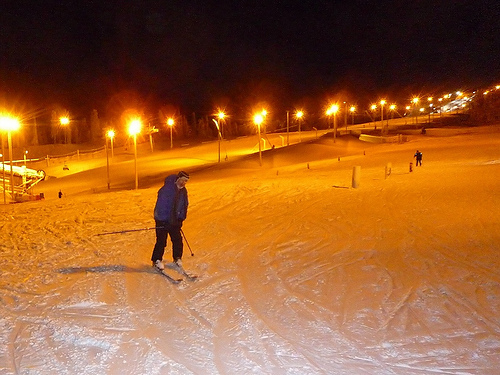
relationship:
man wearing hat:
[149, 169, 190, 272] [173, 170, 188, 182]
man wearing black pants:
[149, 169, 190, 272] [150, 225, 182, 263]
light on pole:
[126, 119, 141, 133] [129, 135, 143, 182]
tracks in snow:
[237, 263, 294, 344] [0, 109, 497, 373]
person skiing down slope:
[393, 110, 447, 204] [6, 124, 498, 373]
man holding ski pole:
[149, 169, 190, 272] [88, 224, 169, 239]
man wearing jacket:
[153, 167, 192, 275] [149, 172, 189, 227]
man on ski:
[149, 169, 190, 272] [157, 269, 182, 284]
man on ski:
[149, 169, 190, 272] [175, 261, 196, 280]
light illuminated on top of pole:
[125, 119, 141, 135] [124, 135, 143, 190]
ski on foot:
[153, 268, 186, 284] [153, 256, 165, 267]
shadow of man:
[55, 265, 157, 277] [151, 169, 192, 270]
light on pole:
[125, 119, 141, 135] [132, 138, 139, 190]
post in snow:
[352, 165, 361, 189] [0, 109, 497, 373]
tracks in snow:
[125, 257, 207, 373] [0, 109, 497, 373]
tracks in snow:
[243, 230, 497, 371] [0, 109, 497, 373]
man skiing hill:
[149, 169, 190, 272] [7, 118, 496, 368]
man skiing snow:
[149, 169, 190, 272] [0, 109, 497, 373]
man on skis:
[149, 169, 190, 272] [157, 256, 204, 288]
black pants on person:
[151, 222, 185, 259] [153, 169, 189, 265]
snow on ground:
[0, 109, 497, 373] [0, 113, 499, 373]